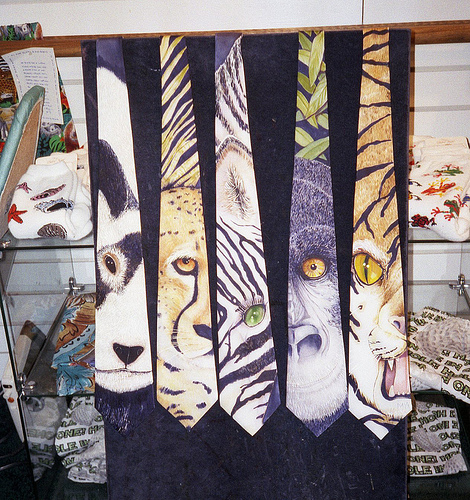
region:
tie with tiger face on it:
[343, 109, 422, 460]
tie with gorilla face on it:
[278, 57, 344, 435]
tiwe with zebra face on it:
[223, 55, 276, 465]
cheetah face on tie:
[148, 162, 212, 433]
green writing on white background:
[62, 395, 116, 496]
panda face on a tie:
[75, 128, 140, 410]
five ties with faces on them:
[90, 162, 410, 441]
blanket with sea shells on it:
[1, 140, 94, 259]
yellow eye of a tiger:
[352, 241, 405, 295]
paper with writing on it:
[3, 29, 59, 158]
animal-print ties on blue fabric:
[88, 29, 418, 485]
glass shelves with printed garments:
[0, 142, 103, 483]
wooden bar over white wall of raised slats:
[0, 0, 456, 453]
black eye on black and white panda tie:
[92, 31, 141, 392]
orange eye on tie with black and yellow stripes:
[142, 32, 210, 423]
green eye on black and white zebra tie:
[207, 26, 272, 424]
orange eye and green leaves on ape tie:
[282, 22, 337, 430]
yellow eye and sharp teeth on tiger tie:
[344, 23, 401, 436]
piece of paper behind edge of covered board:
[0, 27, 60, 173]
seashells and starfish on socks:
[4, 145, 89, 236]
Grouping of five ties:
[89, 26, 408, 434]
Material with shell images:
[8, 164, 81, 242]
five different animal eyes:
[98, 248, 389, 328]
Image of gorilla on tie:
[285, 160, 344, 423]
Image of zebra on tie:
[212, 208, 278, 433]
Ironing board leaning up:
[1, 84, 47, 204]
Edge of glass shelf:
[6, 237, 92, 253]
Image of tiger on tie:
[350, 227, 407, 429]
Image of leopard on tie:
[159, 192, 212, 420]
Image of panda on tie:
[93, 151, 150, 416]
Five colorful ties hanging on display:
[92, 25, 413, 440]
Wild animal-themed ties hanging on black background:
[94, 24, 414, 441]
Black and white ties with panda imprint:
[94, 35, 157, 437]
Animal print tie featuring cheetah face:
[156, 33, 219, 433]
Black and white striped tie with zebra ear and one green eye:
[213, 32, 281, 437]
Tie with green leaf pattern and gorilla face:
[285, 29, 350, 437]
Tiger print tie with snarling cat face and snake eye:
[346, 24, 413, 441]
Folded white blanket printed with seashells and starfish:
[7, 145, 92, 242]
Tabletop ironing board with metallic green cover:
[1, 84, 44, 293]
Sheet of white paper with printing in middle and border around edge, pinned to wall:
[1, 45, 64, 125]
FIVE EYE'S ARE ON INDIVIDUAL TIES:
[96, 252, 398, 327]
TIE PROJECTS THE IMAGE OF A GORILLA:
[287, 73, 348, 451]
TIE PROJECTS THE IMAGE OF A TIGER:
[348, 58, 421, 458]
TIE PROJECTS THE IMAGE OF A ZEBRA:
[211, 80, 283, 411]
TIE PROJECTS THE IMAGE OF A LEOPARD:
[157, 68, 221, 411]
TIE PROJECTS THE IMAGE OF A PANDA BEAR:
[90, 91, 155, 418]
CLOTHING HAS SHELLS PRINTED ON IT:
[13, 144, 88, 244]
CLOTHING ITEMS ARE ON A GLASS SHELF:
[1, 188, 464, 479]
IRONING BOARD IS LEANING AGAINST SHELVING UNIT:
[0, 82, 47, 222]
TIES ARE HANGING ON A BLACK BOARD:
[101, 42, 407, 493]